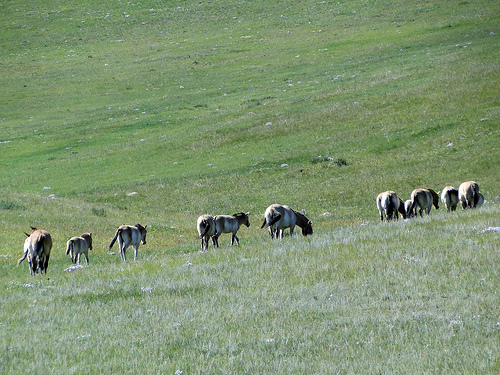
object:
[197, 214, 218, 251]
animal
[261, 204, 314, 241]
animal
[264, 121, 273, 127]
rock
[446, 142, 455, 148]
rock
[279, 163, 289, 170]
rock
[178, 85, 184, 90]
rock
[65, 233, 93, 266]
animals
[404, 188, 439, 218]
horse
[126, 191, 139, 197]
rock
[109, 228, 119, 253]
tail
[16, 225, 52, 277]
horse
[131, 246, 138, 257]
leg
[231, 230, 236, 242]
leg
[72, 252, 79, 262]
leg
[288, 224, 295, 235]
leg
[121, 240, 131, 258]
leg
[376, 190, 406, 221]
horse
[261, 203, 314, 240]
horse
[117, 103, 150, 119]
rocks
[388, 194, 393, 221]
black tail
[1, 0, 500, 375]
grass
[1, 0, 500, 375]
ground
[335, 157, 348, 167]
grass clump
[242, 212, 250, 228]
head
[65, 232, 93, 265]
animal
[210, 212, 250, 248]
animal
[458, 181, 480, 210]
animal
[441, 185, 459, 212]
animal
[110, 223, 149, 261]
animal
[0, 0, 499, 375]
field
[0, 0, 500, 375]
hill